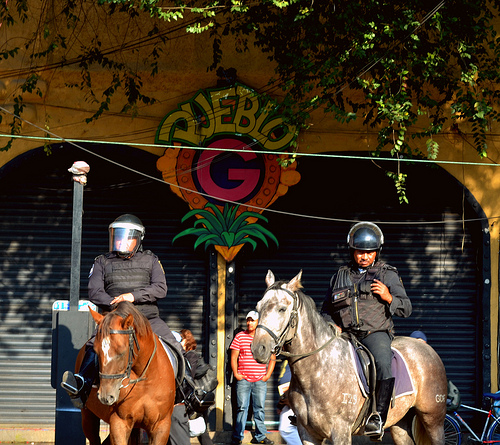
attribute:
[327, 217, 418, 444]
officer — riding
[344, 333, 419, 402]
saddle — purple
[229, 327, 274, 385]
shirt — red, white, striped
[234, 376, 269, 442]
jeans — blue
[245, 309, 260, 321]
hat — white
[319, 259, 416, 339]
jacket — black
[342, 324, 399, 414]
pants — black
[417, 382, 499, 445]
bike — gray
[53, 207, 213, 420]
man — sitting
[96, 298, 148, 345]
mane — brown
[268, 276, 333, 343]
mane — black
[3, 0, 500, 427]
building — large, yellow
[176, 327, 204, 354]
hair — red